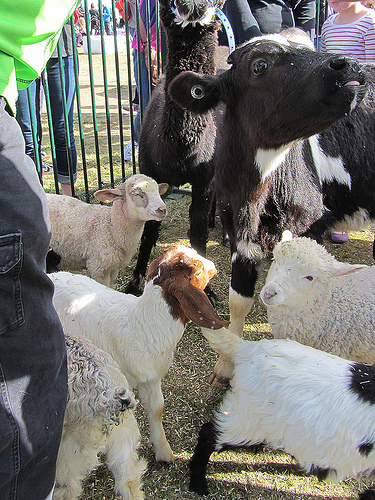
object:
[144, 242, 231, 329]
head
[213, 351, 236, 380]
foot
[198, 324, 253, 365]
tail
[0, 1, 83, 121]
shirt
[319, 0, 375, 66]
child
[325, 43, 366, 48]
stripes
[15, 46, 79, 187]
jeans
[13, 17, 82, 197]
woman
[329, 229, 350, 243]
shoe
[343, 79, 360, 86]
tongue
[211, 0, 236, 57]
tag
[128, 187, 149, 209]
patch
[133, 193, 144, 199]
eye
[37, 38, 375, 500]
ground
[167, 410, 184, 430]
leaves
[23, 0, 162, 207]
gate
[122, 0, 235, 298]
animals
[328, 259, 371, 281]
sheep's ear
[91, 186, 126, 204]
sheep's ear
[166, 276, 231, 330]
sheep's ear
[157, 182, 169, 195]
sheep's ear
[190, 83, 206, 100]
tag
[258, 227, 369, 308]
head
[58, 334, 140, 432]
fur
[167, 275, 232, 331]
brown ear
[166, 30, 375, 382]
animals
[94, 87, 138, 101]
shadows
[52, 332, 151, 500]
goat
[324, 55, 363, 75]
nose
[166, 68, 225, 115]
ear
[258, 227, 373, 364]
animal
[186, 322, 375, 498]
animal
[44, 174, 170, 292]
animal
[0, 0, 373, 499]
zoo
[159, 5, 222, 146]
neck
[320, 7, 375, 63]
shirt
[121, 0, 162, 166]
people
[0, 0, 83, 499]
person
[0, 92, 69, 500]
pants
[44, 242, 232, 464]
goat